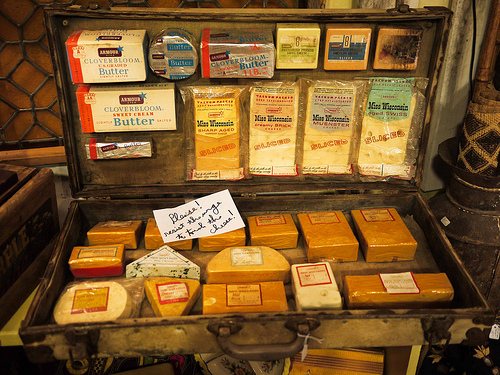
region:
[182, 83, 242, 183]
Miss Wisconsin Sharp Aged Cheese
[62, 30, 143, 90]
Cloverbloom butter stick in white case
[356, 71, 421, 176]
Miss Wisconsin Aged Swiss Cheese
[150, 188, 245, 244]
Small note about cheese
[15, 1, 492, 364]
Luggage full of cheese and butter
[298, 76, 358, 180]
Miss Wisconsin Muenster Cheese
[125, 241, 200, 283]
Spotted triangular aged cheese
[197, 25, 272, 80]
1 pound of Cloverbloom butter.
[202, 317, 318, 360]
Luggage handle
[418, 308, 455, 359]
Luggage buckle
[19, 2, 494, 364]
case full of cheese packets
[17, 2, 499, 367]
battered suitcase containing cheese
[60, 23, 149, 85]
box of butter on top left of suitcase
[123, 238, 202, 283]
white triangle of cheese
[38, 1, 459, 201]
battered lid of suitcase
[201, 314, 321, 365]
handle of battered suitcase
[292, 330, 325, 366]
white tag on suitcase handle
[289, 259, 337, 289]
red and white sticker on cheese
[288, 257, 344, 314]
white rectangular block of cheese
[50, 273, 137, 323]
circular cheese in plastic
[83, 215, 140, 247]
chunk of cheese in suitcase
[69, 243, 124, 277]
chunk of cheese in suitcase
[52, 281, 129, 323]
chunk of cheese in suitcase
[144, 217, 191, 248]
chunk of cheese in suitcase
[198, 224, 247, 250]
chunk of cheese in suitcase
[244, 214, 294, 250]
chunk of cheese in suitcase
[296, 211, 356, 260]
chunk of cheese in suitcase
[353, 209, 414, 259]
chunk of cheese in suitcase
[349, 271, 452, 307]
chunk of cheese in suitcase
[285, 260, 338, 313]
chunk of cheese in suitcase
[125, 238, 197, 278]
green and white cheese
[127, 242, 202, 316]
triangle shaped cheese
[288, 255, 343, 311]
block of white cheese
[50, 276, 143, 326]
circle white heese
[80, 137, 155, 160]
a stick of butter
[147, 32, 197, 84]
round butter block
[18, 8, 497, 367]
a suitcase of cheese and butter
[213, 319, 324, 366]
handle of case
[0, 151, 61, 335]
box to left of case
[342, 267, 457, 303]
cheese on far right in front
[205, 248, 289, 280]
Half moon shaped yellow cheese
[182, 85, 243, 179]
Clear bag with yellow cheese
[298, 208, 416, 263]
Two bricks of yellow cheese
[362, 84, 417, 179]
Bag with green label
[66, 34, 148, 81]
Package of butter in top of case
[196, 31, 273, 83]
Silver package with red trim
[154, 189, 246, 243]
White paper with a note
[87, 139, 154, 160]
Small rectangular package of butter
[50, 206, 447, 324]
Several bricks of cheese in a case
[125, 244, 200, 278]
Triangle shaped block of cheese